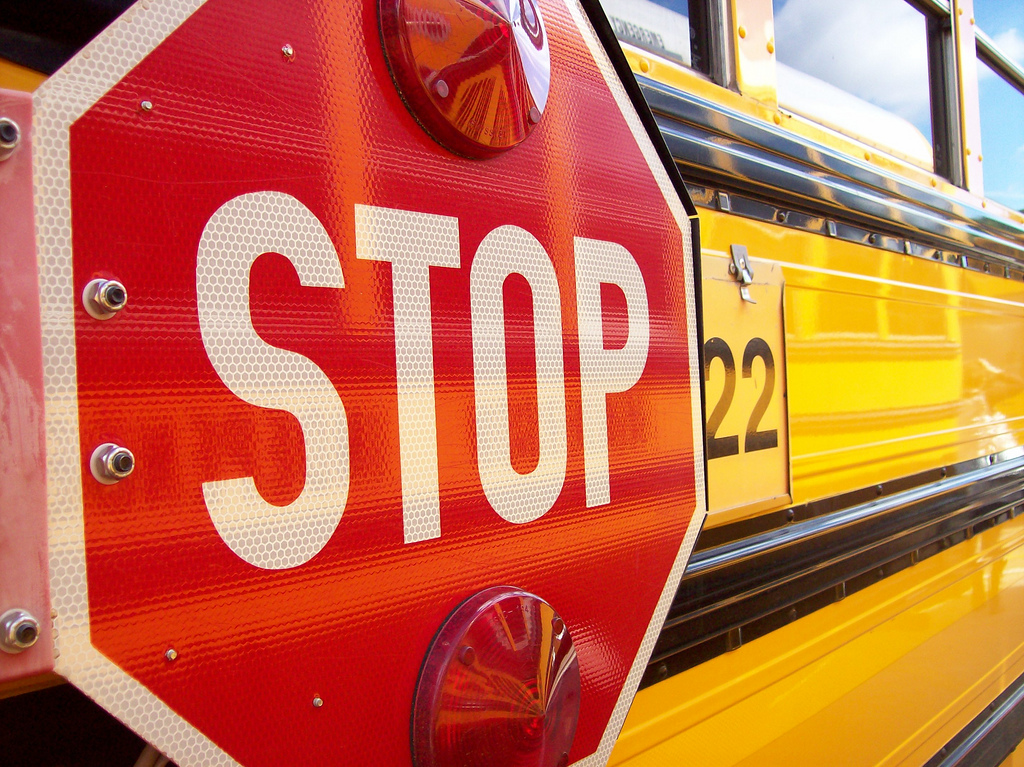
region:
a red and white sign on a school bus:
[114, 128, 684, 601]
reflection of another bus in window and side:
[596, 2, 1017, 600]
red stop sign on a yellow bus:
[9, 7, 958, 764]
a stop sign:
[157, 172, 655, 599]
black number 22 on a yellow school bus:
[686, 321, 789, 477]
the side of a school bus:
[599, 59, 1010, 759]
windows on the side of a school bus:
[682, 0, 1018, 261]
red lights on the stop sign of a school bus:
[338, 2, 583, 177]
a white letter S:
[164, 185, 355, 596]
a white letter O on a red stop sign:
[464, 215, 573, 560]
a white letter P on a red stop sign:
[566, 204, 659, 534]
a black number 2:
[735, 330, 790, 460]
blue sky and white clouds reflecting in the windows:
[806, 11, 1022, 185]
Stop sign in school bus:
[27, 10, 988, 750]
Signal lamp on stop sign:
[353, 586, 626, 764]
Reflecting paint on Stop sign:
[46, 573, 263, 736]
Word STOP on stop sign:
[158, 146, 653, 571]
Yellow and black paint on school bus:
[838, 446, 984, 719]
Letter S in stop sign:
[149, 155, 349, 608]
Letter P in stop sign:
[562, 216, 667, 533]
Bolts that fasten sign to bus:
[57, 240, 147, 520]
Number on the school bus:
[702, 323, 840, 494]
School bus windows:
[733, 7, 1022, 230]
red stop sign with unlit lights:
[21, 1, 724, 760]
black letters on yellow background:
[695, 321, 790, 462]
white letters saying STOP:
[168, 178, 656, 584]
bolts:
[72, 260, 156, 508]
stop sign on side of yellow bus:
[24, 1, 1008, 764]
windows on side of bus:
[778, 1, 1014, 252]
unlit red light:
[397, 579, 593, 760]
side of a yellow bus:
[686, 65, 1018, 762]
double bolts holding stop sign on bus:
[78, 247, 152, 516]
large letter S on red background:
[173, 175, 360, 587]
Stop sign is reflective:
[28, 2, 709, 762]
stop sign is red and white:
[27, 0, 710, 762]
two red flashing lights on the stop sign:
[366, 3, 585, 765]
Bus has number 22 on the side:
[693, 312, 783, 471]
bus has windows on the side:
[603, 0, 1015, 226]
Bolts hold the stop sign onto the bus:
[72, 264, 146, 495]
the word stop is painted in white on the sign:
[185, 182, 653, 568]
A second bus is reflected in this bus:
[617, 12, 990, 513]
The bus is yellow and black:
[573, 3, 1016, 763]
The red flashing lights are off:
[368, 2, 591, 759]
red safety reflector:
[403, 574, 574, 761]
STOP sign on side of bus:
[30, 0, 704, 756]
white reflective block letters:
[187, 181, 644, 558]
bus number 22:
[694, 280, 775, 499]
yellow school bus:
[599, 2, 1015, 762]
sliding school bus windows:
[592, 2, 1020, 206]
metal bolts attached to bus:
[74, 270, 135, 486]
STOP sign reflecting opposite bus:
[71, 2, 682, 669]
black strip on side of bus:
[637, 447, 1020, 692]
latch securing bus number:
[729, 238, 761, 306]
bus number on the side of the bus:
[695, 336, 787, 473]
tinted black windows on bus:
[783, 2, 948, 170]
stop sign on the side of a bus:
[101, 127, 678, 581]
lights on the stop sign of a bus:
[426, 599, 581, 764]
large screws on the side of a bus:
[5, 611, 40, 653]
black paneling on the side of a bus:
[651, 87, 1022, 231]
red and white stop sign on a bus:
[130, 19, 706, 738]